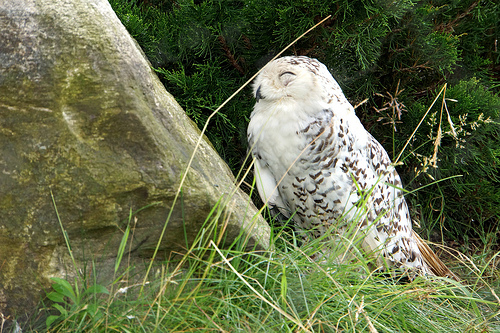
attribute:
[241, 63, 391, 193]
owl — white, sleepy, black, sitting, sleeping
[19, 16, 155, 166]
rock — green, grey, brown, yellow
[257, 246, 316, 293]
grass — green, yellow, long